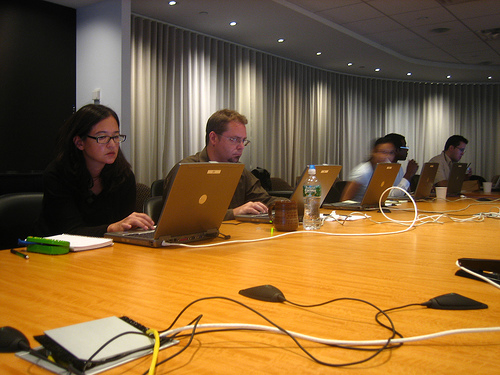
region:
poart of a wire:
[357, 292, 372, 308]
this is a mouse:
[422, 287, 482, 307]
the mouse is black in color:
[450, 299, 459, 304]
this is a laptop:
[120, 152, 242, 235]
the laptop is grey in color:
[183, 212, 193, 224]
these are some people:
[59, 101, 456, 187]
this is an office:
[31, 60, 442, 332]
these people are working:
[58, 113, 430, 242]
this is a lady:
[73, 66, 198, 258]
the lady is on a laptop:
[63, 88, 183, 248]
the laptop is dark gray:
[121, 139, 218, 224]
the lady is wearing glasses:
[58, 104, 135, 254]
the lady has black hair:
[65, 94, 135, 206]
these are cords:
[93, 267, 378, 361]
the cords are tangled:
[73, 289, 377, 369]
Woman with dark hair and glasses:
[44, 101, 155, 241]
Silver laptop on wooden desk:
[108, 161, 244, 249]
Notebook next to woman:
[36, 231, 113, 252]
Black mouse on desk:
[236, 283, 285, 303]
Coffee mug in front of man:
[262, 198, 299, 232]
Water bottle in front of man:
[300, 164, 320, 229]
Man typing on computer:
[153, 108, 274, 218]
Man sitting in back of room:
[420, 134, 477, 198]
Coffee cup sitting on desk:
[432, 181, 447, 201]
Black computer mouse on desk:
[421, 291, 488, 312]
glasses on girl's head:
[70, 114, 137, 169]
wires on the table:
[216, 267, 416, 365]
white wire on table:
[410, 307, 494, 362]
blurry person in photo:
[317, 121, 421, 211]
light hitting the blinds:
[98, 59, 223, 141]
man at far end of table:
[423, 118, 480, 193]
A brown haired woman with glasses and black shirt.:
[37, 103, 153, 235]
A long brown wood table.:
[2, 190, 499, 373]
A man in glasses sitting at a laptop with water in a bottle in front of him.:
[162, 108, 274, 218]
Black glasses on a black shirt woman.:
[75, 129, 125, 144]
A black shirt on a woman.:
[40, 148, 136, 240]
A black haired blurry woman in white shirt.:
[340, 135, 398, 202]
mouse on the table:
[240, 281, 282, 305]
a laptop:
[175, 162, 237, 236]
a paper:
[68, 323, 115, 351]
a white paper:
[65, 321, 91, 352]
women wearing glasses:
[94, 134, 127, 142]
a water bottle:
[300, 165, 330, 228]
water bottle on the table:
[292, 167, 330, 234]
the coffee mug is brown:
[267, 198, 299, 234]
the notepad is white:
[27, 232, 113, 252]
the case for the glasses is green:
[18, 236, 70, 254]